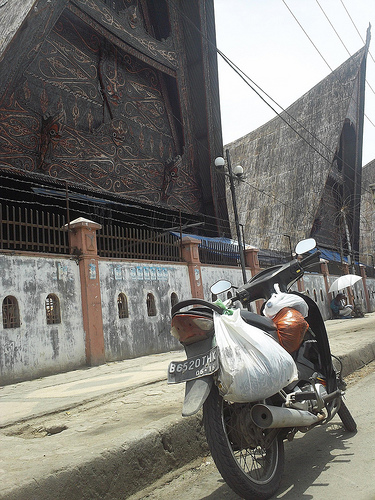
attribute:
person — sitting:
[329, 292, 352, 317]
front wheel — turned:
[325, 389, 358, 436]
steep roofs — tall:
[3, 2, 373, 265]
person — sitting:
[328, 291, 356, 315]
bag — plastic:
[212, 298, 297, 403]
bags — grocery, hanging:
[209, 277, 321, 405]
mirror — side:
[293, 236, 318, 255]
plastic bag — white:
[260, 281, 311, 318]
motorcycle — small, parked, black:
[168, 237, 358, 498]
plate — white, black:
[167, 350, 223, 385]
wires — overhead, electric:
[215, 2, 373, 144]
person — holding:
[329, 285, 359, 326]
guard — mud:
[174, 371, 225, 417]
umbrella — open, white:
[326, 268, 359, 314]